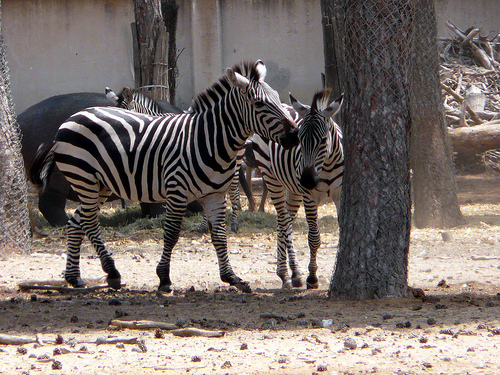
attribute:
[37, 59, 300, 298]
zebra — black, white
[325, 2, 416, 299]
tree — here, brown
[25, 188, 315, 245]
grass — dry, growing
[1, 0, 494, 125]
wall — dilapidated, concrete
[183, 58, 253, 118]
mane — black, white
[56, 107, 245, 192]
stripes — black, white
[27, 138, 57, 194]
tail — black, white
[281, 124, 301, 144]
nose — black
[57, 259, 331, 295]
hooves — black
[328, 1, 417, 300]
bark — rough, grey, black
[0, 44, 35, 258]
fence — chain link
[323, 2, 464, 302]
trees — standing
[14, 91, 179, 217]
animal — black